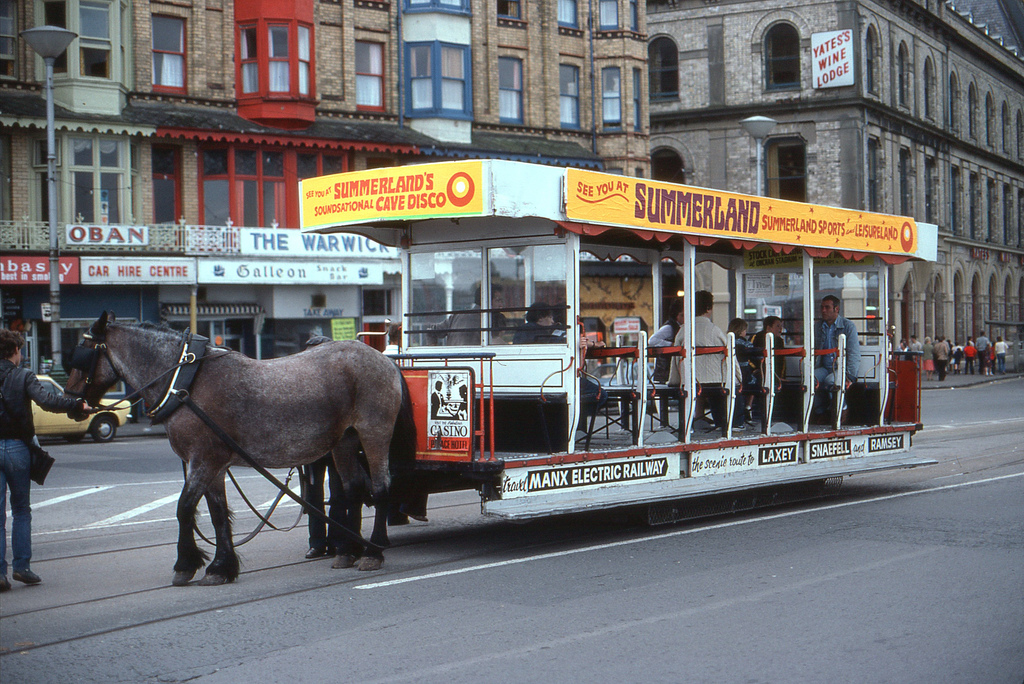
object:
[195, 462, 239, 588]
horse's legs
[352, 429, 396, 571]
horse's legs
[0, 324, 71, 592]
man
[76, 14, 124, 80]
window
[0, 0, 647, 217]
apartment building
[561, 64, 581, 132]
window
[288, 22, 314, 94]
window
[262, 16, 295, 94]
window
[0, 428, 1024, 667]
street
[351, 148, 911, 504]
trolley car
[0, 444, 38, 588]
jeans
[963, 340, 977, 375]
person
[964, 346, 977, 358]
shirt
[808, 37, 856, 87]
letters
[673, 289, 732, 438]
woman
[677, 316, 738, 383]
sweater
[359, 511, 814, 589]
line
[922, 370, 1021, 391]
curb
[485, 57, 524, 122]
window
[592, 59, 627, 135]
window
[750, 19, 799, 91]
window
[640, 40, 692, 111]
window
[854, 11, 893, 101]
window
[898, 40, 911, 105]
window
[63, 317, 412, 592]
horse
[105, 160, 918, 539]
trolley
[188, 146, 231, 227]
windows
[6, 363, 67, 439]
jacket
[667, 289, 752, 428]
people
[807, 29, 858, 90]
sign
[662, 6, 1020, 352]
building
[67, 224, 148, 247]
sign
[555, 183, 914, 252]
signs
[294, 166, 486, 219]
sign